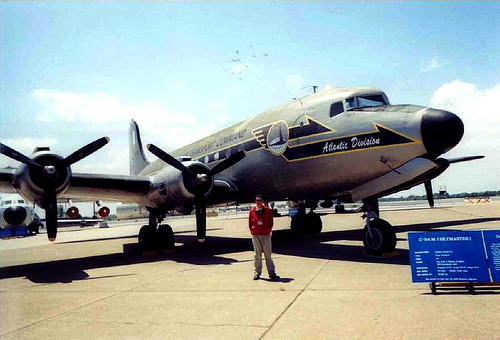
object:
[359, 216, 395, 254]
wheel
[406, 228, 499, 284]
sign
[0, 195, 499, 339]
ground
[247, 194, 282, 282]
man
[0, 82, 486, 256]
airplane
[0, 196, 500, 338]
runway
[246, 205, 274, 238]
coat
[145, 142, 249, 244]
propellers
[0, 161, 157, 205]
wing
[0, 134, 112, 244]
propeller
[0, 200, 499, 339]
tarmac